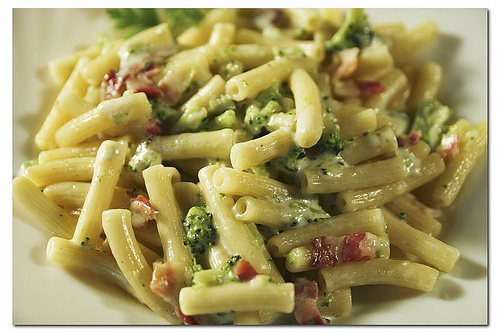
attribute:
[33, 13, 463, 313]
salad — yellow, slimey, pasta, green, on plate, hot, tender, creamy, white, fresh, brown, gold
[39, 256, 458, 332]
plate — white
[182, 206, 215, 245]
boccoli — green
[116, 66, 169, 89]
bacon — tender, red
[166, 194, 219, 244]
broccoli — green, steaming, well cooked